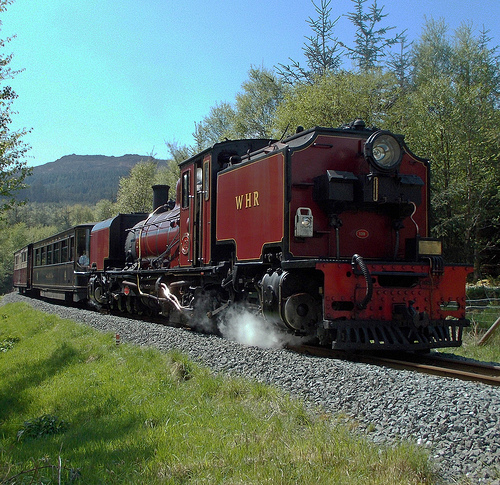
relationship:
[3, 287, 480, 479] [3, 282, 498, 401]
gravel on tracks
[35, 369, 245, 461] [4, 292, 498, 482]
grass on ground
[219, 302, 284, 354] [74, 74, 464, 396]
smoke coming off train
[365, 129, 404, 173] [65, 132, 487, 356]
headlight on train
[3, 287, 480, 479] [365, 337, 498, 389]
gravel around tracks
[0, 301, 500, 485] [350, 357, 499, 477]
grass beside gravel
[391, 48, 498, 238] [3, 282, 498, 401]
tree beside tracks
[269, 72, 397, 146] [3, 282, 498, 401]
tree beside tracks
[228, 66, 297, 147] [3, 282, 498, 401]
tree beside tracks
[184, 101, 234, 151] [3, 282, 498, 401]
tree beside tracks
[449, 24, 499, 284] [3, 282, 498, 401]
tree beside tracks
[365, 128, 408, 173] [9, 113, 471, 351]
headlight on locomotive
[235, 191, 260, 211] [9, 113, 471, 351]
words are on locomotive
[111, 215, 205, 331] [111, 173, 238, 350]
engine on locomotive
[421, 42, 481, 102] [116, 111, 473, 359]
trees are behind locomotive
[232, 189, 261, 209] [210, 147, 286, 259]
words written on plate